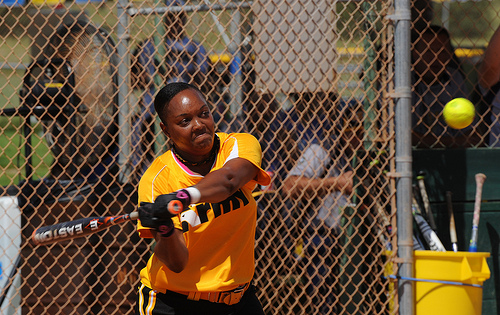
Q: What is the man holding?
A: A bat.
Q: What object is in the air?
A: Tennis ball.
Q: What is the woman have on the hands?
A: Gloves.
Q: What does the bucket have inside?
A: Bats.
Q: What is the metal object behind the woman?
A: Fence.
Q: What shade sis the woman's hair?
A: Black.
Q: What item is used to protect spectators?
A: A fence.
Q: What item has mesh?
A: A fence.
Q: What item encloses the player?
A: A fence.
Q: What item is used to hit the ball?
A: A bat.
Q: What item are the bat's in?
A: A bucket.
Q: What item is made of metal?
A: A fence.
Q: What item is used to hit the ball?
A: A bat.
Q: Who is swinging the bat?
A: A female player.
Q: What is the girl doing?
A: Playing ball.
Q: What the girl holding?
A: A bat.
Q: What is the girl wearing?
A: A jersey.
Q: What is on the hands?
A: Gloves.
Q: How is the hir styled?
A: Ponytail.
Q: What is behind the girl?
A: A fence.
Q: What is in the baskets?
A: Bats.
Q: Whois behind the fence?
A: The audience.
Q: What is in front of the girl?
A: A ball.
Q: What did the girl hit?
A: A ball.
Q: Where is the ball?
A: In mid air.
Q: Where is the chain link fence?
A: Behind the batter.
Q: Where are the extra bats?
A: In the yellow bucket/.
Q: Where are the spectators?
A: Behind the fence.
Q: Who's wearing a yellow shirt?
A: The player.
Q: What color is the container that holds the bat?
A: Yellow.